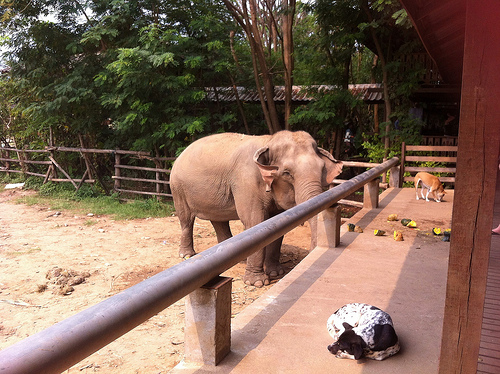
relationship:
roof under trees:
[198, 75, 384, 107] [2, 3, 443, 183]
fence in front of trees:
[0, 124, 382, 222] [0, 1, 453, 203]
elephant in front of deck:
[164, 126, 343, 290] [0, 140, 457, 372]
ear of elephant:
[252, 142, 280, 194] [164, 126, 343, 290]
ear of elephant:
[316, 145, 344, 187] [164, 126, 343, 290]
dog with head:
[412, 171, 448, 205] [432, 189, 449, 203]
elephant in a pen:
[164, 126, 343, 290] [1, 130, 392, 369]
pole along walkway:
[1, 157, 400, 371] [167, 177, 455, 373]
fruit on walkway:
[376, 227, 388, 237] [167, 177, 455, 373]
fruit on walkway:
[401, 218, 416, 228] [167, 177, 455, 373]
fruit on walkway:
[395, 229, 405, 241] [167, 177, 455, 373]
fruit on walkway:
[433, 227, 453, 243] [167, 177, 455, 373]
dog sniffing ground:
[326, 303, 401, 361] [176, 134, 443, 345]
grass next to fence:
[37, 193, 164, 225] [2, 148, 172, 201]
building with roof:
[180, 85, 380, 147] [204, 84, 385, 103]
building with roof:
[397, 4, 497, 372] [204, 84, 385, 103]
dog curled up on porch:
[326, 303, 401, 361] [167, 176, 452, 372]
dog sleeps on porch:
[322, 300, 404, 365] [326, 230, 458, 325]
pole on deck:
[1, 157, 400, 371] [198, 175, 484, 371]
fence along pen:
[3, 127, 387, 229] [1, 130, 392, 369]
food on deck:
[344, 210, 451, 244] [180, 185, 453, 373]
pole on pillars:
[1, 157, 400, 371] [187, 276, 232, 368]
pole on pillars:
[1, 157, 400, 371] [316, 201, 341, 252]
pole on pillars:
[1, 157, 400, 371] [362, 180, 379, 212]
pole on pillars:
[1, 157, 400, 371] [387, 165, 400, 189]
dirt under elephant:
[2, 186, 359, 372] [164, 126, 343, 290]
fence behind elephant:
[0, 124, 382, 222] [167, 129, 341, 274]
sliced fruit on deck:
[427, 218, 442, 244] [211, 149, 453, 371]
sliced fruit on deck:
[401, 212, 414, 230] [211, 149, 453, 371]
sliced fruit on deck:
[386, 214, 398, 221] [211, 149, 453, 371]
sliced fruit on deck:
[363, 227, 380, 239] [211, 149, 453, 371]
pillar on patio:
[435, 0, 499, 372] [158, 180, 498, 371]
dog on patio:
[322, 300, 404, 365] [167, 187, 454, 374]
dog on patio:
[414, 172, 448, 203] [167, 187, 454, 374]